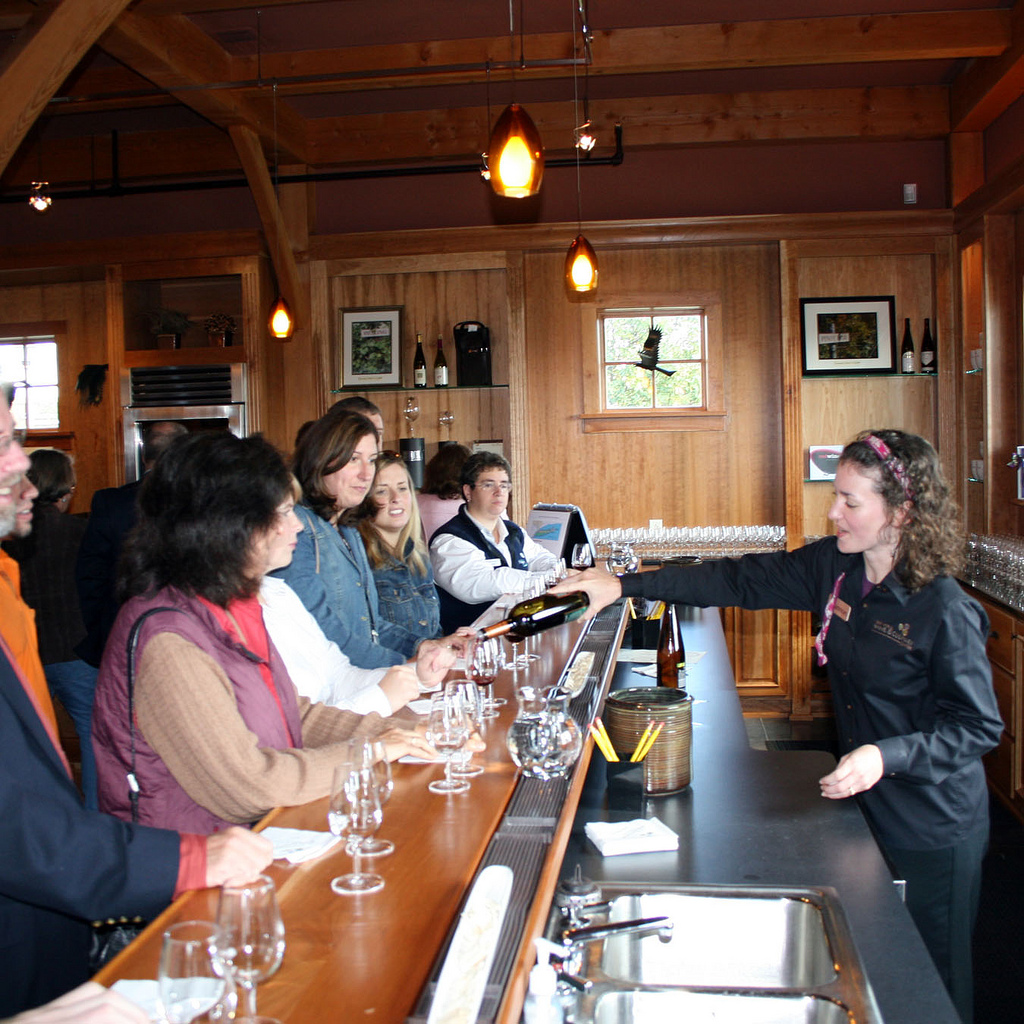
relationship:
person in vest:
[358, 451, 444, 640] [82, 590, 316, 843]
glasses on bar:
[321, 774, 395, 909] [41, 551, 638, 1022]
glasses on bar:
[343, 737, 406, 858] [41, 551, 638, 1022]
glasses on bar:
[417, 685, 476, 796] [41, 551, 638, 1022]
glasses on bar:
[203, 869, 297, 1021] [41, 551, 638, 1022]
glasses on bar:
[144, 914, 238, 1021] [41, 551, 638, 1022]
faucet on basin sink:
[557, 915, 674, 968] [559, 881, 883, 1022]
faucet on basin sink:
[563, 916, 669, 937] [559, 881, 883, 1022]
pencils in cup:
[571, 709, 671, 764] [604, 755, 646, 808]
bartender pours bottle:
[534, 402, 1021, 971] [477, 590, 590, 642]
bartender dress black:
[534, 402, 1021, 971] [613, 533, 1011, 953]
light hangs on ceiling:
[560, 198, 604, 302] [229, 26, 947, 223]